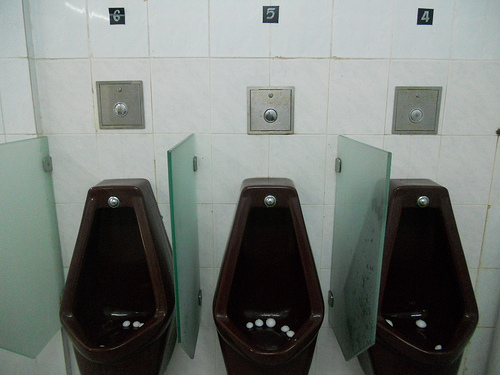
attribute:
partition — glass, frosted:
[322, 132, 394, 361]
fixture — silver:
[248, 86, 295, 136]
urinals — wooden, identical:
[75, 213, 173, 343]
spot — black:
[493, 128, 498, 138]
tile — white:
[146, 53, 212, 142]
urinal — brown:
[356, 147, 489, 372]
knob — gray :
[404, 192, 429, 204]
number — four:
[418, 7, 434, 25]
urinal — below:
[371, 82, 497, 373]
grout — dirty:
[219, 53, 354, 63]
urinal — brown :
[208, 165, 325, 371]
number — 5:
[259, 4, 279, 24]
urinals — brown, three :
[71, 174, 458, 374]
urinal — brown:
[58, 176, 222, 344]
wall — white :
[1, 5, 498, 162]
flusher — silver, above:
[255, 100, 287, 126]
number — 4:
[413, 6, 443, 31]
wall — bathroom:
[24, 4, 494, 154]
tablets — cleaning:
[238, 312, 300, 342]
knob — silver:
[89, 187, 136, 211]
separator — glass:
[320, 127, 396, 372]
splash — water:
[349, 220, 377, 353]